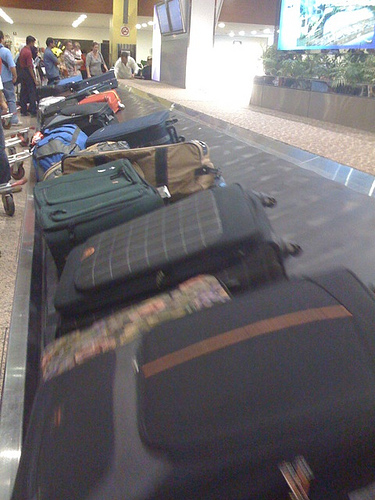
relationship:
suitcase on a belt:
[50, 185, 283, 304] [288, 162, 371, 271]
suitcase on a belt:
[85, 117, 178, 144] [272, 160, 364, 275]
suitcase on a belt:
[81, 87, 128, 110] [287, 146, 374, 268]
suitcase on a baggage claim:
[6, 264, 370, 494] [33, 40, 371, 498]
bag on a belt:
[32, 123, 86, 180] [282, 133, 373, 270]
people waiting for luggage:
[6, 36, 135, 85] [46, 61, 373, 492]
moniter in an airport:
[153, 3, 188, 34] [10, 4, 372, 498]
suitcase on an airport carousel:
[6, 264, 370, 494] [16, 56, 359, 496]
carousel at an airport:
[12, 69, 357, 487] [10, 4, 372, 498]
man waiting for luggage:
[22, 32, 36, 115] [28, 274, 373, 496]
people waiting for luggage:
[6, 36, 135, 85] [4, 263, 372, 495]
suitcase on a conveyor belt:
[6, 264, 370, 494] [265, 156, 372, 275]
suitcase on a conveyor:
[33, 156, 155, 240] [224, 122, 371, 274]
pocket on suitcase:
[70, 186, 226, 295] [51, 180, 307, 330]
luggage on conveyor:
[30, 156, 165, 267] [28, 64, 368, 494]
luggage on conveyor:
[52, 177, 304, 344] [28, 64, 368, 494]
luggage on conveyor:
[4, 263, 372, 495] [28, 64, 368, 494]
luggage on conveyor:
[56, 137, 225, 207] [28, 64, 368, 494]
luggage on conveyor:
[28, 119, 87, 177] [28, 64, 368, 494]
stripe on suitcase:
[139, 301, 353, 380] [6, 264, 370, 494]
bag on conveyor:
[30, 121, 87, 179] [2, 75, 371, 494]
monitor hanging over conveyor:
[272, 2, 372, 53] [248, 67, 373, 136]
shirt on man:
[42, 47, 60, 82] [41, 35, 67, 90]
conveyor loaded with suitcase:
[2, 75, 371, 494] [6, 264, 370, 494]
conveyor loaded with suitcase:
[2, 75, 371, 494] [31, 272, 233, 387]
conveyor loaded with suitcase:
[2, 75, 371, 494] [50, 185, 283, 304]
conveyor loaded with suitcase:
[2, 75, 371, 494] [33, 156, 155, 240]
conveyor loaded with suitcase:
[2, 75, 371, 494] [83, 106, 186, 148]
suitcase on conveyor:
[6, 264, 370, 494] [2, 75, 371, 494]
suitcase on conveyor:
[31, 272, 233, 387] [2, 75, 371, 494]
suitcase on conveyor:
[50, 185, 283, 304] [2, 75, 371, 494]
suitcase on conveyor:
[33, 156, 155, 240] [2, 75, 371, 494]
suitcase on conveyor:
[58, 136, 224, 206] [2, 75, 371, 494]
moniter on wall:
[153, 3, 188, 34] [150, 1, 214, 96]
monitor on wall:
[272, 2, 372, 53] [217, 4, 371, 62]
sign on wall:
[120, 21, 130, 37] [107, 1, 136, 72]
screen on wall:
[151, 0, 188, 38] [148, 10, 196, 71]